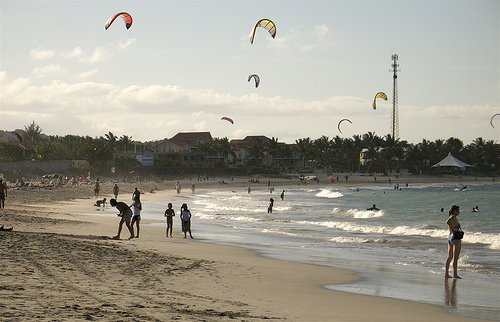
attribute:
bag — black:
[454, 229, 464, 239]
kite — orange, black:
[105, 12, 135, 32]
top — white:
[420, 147, 474, 169]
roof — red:
[172, 130, 209, 145]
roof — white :
[432, 152, 469, 172]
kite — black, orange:
[248, 8, 279, 55]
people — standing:
[163, 191, 205, 251]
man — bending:
[93, 190, 141, 238]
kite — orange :
[90, 1, 296, 58]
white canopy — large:
[429, 151, 474, 176]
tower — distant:
[359, 48, 411, 158]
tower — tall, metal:
[380, 40, 410, 130]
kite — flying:
[247, 15, 279, 45]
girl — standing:
[436, 205, 468, 286]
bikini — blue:
[445, 221, 465, 254]